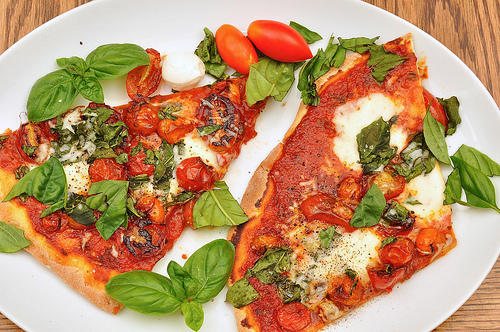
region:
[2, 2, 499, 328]
white plate with two slices of pizza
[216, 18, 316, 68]
two red grape tomato garnish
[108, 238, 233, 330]
basil leaves used as garnish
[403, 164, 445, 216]
melted white cheese on a pizza slice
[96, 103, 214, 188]
cooked tomatoes on a pizza slice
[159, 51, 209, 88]
white mozzarella cheese ball as garnish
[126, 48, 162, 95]
half of a red grape tomato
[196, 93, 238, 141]
sliced red onion on a pizza slice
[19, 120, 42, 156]
slice of mushroom on a pizza slice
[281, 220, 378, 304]
melted white cheese with spices on top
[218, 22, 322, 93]
red tomatoes on plate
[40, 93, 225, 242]
red tomatoes on pizza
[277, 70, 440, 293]
green basil on pizza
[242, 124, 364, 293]
red sauce on pizza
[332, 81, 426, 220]
white cheese on pizza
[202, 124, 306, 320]
crust is dark brown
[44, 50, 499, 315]
pizza on white plate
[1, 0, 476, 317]
plate on brown table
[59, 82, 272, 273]
charred tomatoes on pizza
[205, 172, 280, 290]
brown and black crust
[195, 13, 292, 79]
red tomatoes on plate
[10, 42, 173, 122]
green basil on plate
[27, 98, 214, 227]
white cheese on pizza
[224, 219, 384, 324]
white and melted cheese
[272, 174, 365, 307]
red sauce on pizza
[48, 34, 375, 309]
two slices of pizza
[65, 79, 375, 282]
charred vegetables on pizza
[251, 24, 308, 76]
Red tomato on white plate.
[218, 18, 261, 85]
Red tomato on plate.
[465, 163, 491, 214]
Green basil leaf on plate.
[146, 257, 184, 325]
Green basil leaf on white plate.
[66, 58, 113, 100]
Green basil leaf on plate.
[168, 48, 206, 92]
Piece of white cheese on plate.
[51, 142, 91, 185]
White cheese on pizza.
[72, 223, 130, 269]
Red sauce on pizza.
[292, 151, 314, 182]
Red sauce on pizza.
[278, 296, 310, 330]
Red tomato on pizza.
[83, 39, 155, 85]
The leaf is green.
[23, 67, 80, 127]
The leaf is green.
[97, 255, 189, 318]
The leaf is green.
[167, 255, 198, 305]
The leaf is green.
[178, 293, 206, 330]
The leaf is green.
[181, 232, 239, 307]
The leaf is green.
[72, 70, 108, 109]
The leaf is green.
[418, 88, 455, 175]
The leaf is green.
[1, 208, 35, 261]
The leaf is green.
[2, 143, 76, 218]
The leaf is green.